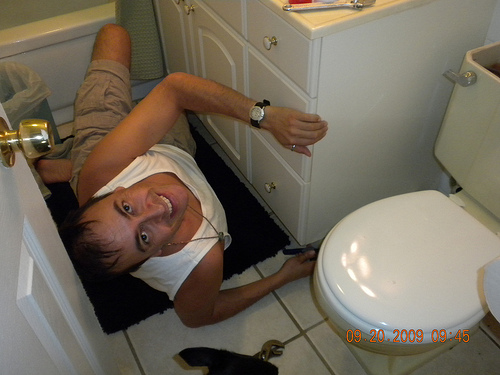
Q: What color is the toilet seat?
A: White.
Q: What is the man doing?
A: Smiling.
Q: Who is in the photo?
A: A man.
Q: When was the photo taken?
A: During the day.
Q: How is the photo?
A: Clear.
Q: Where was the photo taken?
A: In a bathroom at a home.